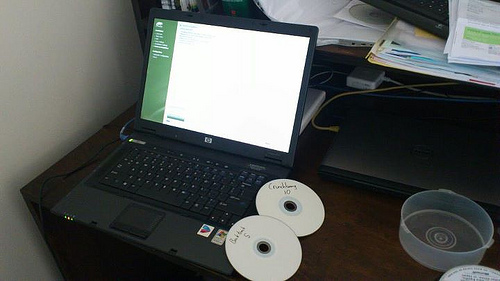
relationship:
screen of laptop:
[157, 25, 296, 146] [67, 6, 302, 260]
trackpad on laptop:
[114, 201, 172, 239] [67, 6, 302, 260]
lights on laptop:
[123, 132, 135, 142] [67, 6, 302, 260]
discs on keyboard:
[244, 206, 302, 248] [107, 161, 208, 187]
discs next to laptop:
[244, 206, 302, 248] [67, 6, 302, 260]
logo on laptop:
[127, 122, 148, 130] [67, 6, 302, 260]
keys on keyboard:
[111, 155, 166, 181] [107, 161, 208, 187]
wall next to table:
[38, 28, 79, 50] [91, 128, 104, 134]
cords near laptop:
[375, 76, 451, 109] [67, 6, 302, 260]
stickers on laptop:
[195, 226, 226, 245] [67, 6, 302, 260]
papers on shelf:
[369, 28, 428, 70] [332, 52, 356, 67]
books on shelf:
[456, 24, 491, 48] [332, 52, 356, 67]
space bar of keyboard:
[144, 192, 183, 208] [107, 161, 208, 187]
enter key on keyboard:
[230, 195, 246, 209] [107, 161, 208, 187]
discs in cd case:
[244, 206, 302, 248] [407, 199, 462, 240]